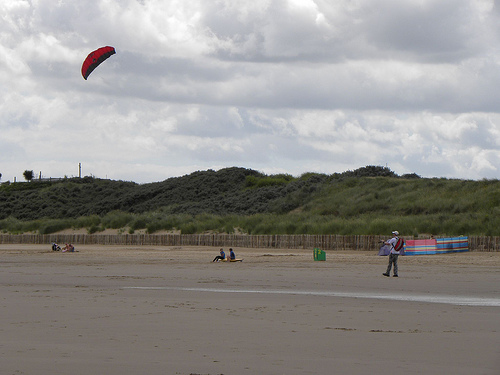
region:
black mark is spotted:
[197, 351, 214, 361]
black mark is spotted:
[201, 343, 215, 369]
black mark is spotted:
[203, 351, 221, 368]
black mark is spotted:
[199, 345, 210, 365]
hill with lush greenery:
[0, 179, 495, 236]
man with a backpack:
[380, 228, 402, 277]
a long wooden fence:
[0, 229, 499, 248]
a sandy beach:
[0, 243, 498, 359]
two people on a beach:
[46, 240, 76, 253]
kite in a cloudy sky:
[70, 35, 126, 85]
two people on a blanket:
[210, 245, 240, 265]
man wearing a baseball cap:
[381, 230, 403, 277]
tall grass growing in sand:
[2, 210, 215, 232]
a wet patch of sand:
[115, 277, 497, 316]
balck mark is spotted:
[341, 318, 350, 343]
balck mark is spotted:
[370, 327, 381, 340]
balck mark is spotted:
[379, 318, 389, 345]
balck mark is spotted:
[375, 322, 390, 351]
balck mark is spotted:
[364, 327, 384, 347]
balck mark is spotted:
[373, 326, 385, 339]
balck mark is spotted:
[379, 325, 384, 335]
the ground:
[219, 282, 328, 362]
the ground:
[237, 333, 264, 363]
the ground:
[251, 328, 313, 370]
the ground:
[291, 356, 307, 368]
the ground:
[280, 319, 322, 366]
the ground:
[239, 287, 281, 357]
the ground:
[276, 280, 331, 368]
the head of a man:
[388, 227, 400, 239]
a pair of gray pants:
[383, 251, 401, 276]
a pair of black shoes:
[374, 269, 403, 279]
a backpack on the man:
[388, 234, 407, 251]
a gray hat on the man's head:
[389, 227, 400, 235]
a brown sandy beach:
[0, 242, 499, 373]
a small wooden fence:
[1, 227, 498, 259]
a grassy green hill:
[0, 162, 499, 238]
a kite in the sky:
[78, 41, 119, 88]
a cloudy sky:
[1, 0, 498, 191]